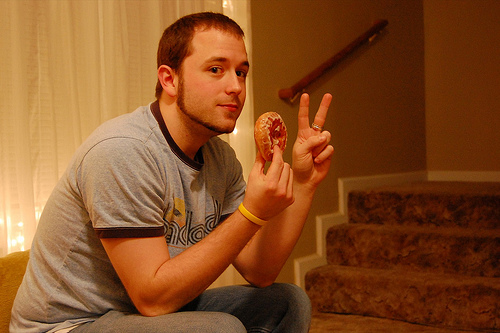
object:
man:
[9, 12, 321, 331]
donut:
[254, 107, 288, 161]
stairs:
[295, 180, 498, 332]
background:
[1, 2, 499, 331]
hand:
[240, 144, 294, 221]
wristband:
[233, 202, 269, 228]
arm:
[80, 143, 251, 317]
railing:
[276, 16, 394, 107]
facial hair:
[173, 68, 239, 136]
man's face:
[176, 19, 248, 133]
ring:
[311, 123, 322, 133]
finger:
[313, 92, 331, 131]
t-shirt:
[9, 102, 255, 332]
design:
[154, 194, 223, 246]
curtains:
[0, 0, 241, 260]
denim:
[67, 280, 313, 332]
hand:
[290, 93, 335, 180]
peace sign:
[293, 90, 335, 133]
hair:
[146, 11, 246, 100]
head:
[154, 13, 251, 137]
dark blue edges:
[146, 97, 208, 173]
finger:
[296, 92, 313, 130]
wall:
[252, 1, 499, 267]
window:
[3, 0, 234, 262]